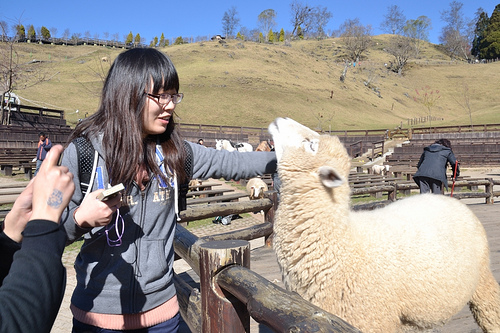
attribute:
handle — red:
[450, 142, 466, 205]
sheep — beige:
[262, 112, 498, 328]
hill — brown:
[179, 12, 383, 123]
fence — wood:
[162, 224, 282, 330]